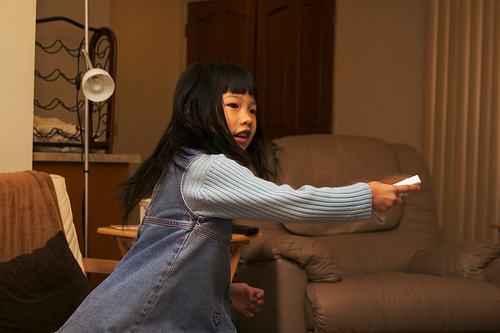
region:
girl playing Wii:
[62, 46, 434, 331]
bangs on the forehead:
[219, 72, 259, 94]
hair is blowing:
[105, 138, 152, 232]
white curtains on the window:
[413, 3, 498, 250]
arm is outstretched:
[188, 153, 373, 228]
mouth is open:
[231, 126, 253, 140]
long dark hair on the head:
[107, 56, 284, 230]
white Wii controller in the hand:
[364, 166, 433, 221]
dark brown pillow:
[0, 231, 85, 331]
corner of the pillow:
[46, 225, 81, 245]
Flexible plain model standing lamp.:
[78, 47, 114, 257]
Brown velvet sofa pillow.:
[0, 232, 95, 332]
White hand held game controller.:
[373, 172, 421, 228]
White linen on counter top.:
[32, 114, 99, 151]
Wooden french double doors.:
[185, 0, 330, 140]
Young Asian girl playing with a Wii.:
[57, 59, 422, 331]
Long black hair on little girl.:
[119, 63, 271, 225]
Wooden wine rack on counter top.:
[35, 13, 119, 153]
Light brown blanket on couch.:
[0, 165, 70, 262]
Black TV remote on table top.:
[235, 225, 257, 235]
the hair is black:
[139, 59, 261, 165]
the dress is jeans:
[68, 144, 228, 331]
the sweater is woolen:
[203, 159, 371, 221]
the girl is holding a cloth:
[394, 175, 427, 199]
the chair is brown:
[288, 139, 498, 319]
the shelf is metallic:
[27, 17, 120, 154]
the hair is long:
[138, 70, 266, 195]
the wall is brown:
[351, 4, 483, 149]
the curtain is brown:
[430, 6, 497, 228]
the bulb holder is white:
[84, 72, 118, 102]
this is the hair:
[190, 73, 211, 123]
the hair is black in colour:
[184, 80, 217, 102]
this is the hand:
[221, 183, 403, 212]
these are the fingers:
[244, 287, 265, 315]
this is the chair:
[270, 227, 499, 315]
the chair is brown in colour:
[273, 247, 498, 330]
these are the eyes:
[227, 99, 258, 116]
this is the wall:
[132, 49, 166, 127]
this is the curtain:
[445, 95, 492, 214]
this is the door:
[210, 20, 334, 54]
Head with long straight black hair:
[108, 56, 280, 238]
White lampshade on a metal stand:
[73, 56, 116, 282]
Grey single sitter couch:
[237, 127, 498, 331]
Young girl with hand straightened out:
[55, 55, 430, 332]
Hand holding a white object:
[360, 171, 423, 221]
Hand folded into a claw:
[222, 281, 269, 323]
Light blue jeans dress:
[47, 138, 241, 331]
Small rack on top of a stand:
[29, 18, 141, 165]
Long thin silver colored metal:
[82, 0, 92, 291]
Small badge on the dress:
[208, 307, 223, 329]